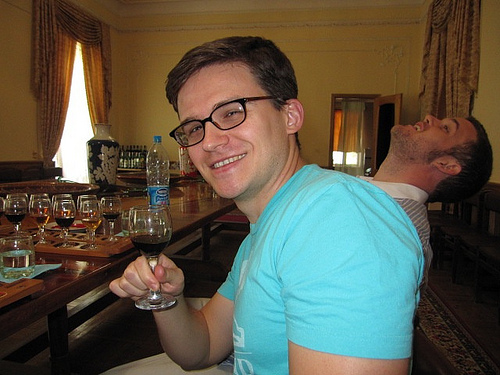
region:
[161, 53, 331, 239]
face of the person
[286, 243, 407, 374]
a man wearing t shirt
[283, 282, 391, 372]
arm of the person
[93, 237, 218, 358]
hand of the person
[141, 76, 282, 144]
spects of the person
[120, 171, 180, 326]
a wine glass holding by man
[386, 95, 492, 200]
a man sleeping in chair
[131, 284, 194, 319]
buttom part of the glass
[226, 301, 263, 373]
a text on the shirt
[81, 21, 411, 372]
the man holding a glass of wine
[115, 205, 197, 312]
the glass is glass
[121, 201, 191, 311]
the glass is clear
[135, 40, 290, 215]
the man wearing glasses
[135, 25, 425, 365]
the man wearing t shirt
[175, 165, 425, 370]
the t shirt is blue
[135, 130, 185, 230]
bottle on the table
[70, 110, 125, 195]
the vase on the table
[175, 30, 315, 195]
the man is smiling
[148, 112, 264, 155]
The man is wearing glasses.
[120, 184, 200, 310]
The man is holding a wine glass.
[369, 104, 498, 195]
The man is leaning his head back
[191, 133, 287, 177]
The man is smiling.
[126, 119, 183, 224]
Woter bottle on the table.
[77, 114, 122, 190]
A vase on the table.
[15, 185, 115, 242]
Glasses of wine on the table.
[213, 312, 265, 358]
White writing on the shirt.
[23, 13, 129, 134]
Curtains over the window.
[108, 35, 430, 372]
man drinking glass of red wine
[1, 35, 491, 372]
two guys at a wine tasting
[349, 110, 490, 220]
man throwing his head back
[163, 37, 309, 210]
man in glasses smiling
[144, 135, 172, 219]
plastic bottle of water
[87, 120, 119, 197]
tall black and white vase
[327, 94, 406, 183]
wooden and black door that is open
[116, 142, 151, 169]
bottle of wine lined up in a row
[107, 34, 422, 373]
guy in a blue shirt drinking wine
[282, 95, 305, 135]
an ear of a man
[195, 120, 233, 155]
a nose of a man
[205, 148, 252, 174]
a mouth of a man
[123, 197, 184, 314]
wine in a wine glass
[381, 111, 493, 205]
a head of a man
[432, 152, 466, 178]
the ear of a man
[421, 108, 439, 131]
the nose of a man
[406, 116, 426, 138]
the mouth of a man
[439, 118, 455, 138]
the eye of man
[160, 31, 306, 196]
A guy smiling at the camera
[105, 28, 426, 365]
A guy holding a glass of wine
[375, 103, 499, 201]
The guy with his head tipped back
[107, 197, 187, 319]
A hand holding a glass of wine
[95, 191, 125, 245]
A glass of red wine on the table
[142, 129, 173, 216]
A bottle of water on the table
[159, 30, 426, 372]
A guy wearing a light blue T-shirt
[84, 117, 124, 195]
A black and white vace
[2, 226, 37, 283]
A Glass of water on the table